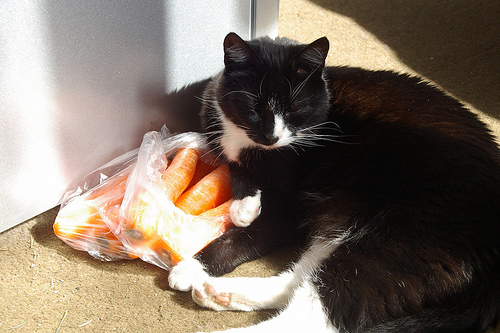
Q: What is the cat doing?
A: Lying down.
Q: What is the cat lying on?
A: Carpet.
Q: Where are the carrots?
A: Next to the cat.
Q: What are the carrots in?
A: A plastic bag.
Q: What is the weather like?
A: Sunny.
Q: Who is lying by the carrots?
A: The cat.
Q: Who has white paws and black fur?
A: The sleeping cat.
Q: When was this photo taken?
A: During the daytime.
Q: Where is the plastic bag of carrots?
A: On the floor.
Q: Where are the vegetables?
A: In the plastic bag.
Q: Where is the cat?
A: Lying on the floor.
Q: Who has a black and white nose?
A: The cat.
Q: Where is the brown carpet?
A: On the floor.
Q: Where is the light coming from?
A: The sun.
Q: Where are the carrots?
A: In the bag.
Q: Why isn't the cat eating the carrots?
A: Cats do not eat carrots?.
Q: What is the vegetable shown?
A: Carrots.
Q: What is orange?
A: Carrots.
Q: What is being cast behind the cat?
A: Shadow.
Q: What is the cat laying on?
A: Carpet.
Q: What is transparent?
A: Bag.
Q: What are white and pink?
A: Paws.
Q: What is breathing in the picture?
A: Cat.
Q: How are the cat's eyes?
A: Closed.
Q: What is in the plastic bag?
A: Carrots.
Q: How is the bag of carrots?
A: Open.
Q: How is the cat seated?
A: Leaning on the carrots.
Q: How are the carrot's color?
A: Orange.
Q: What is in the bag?
A: Carrots.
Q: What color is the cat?
A: Black and white.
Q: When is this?
A: Daytime.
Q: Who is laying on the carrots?
A: The cat.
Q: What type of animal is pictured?
A: A cat.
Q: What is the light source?
A: Sunlight.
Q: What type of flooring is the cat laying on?
A: Carpet.